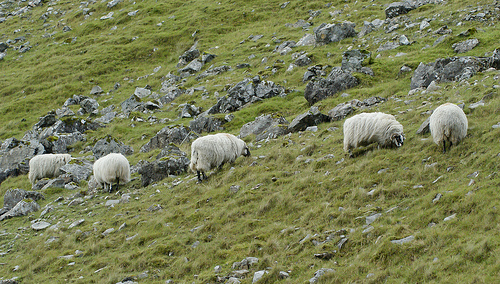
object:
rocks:
[205, 78, 285, 115]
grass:
[0, 0, 500, 283]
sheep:
[343, 111, 404, 152]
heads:
[240, 139, 256, 157]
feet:
[102, 176, 219, 192]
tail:
[103, 162, 120, 184]